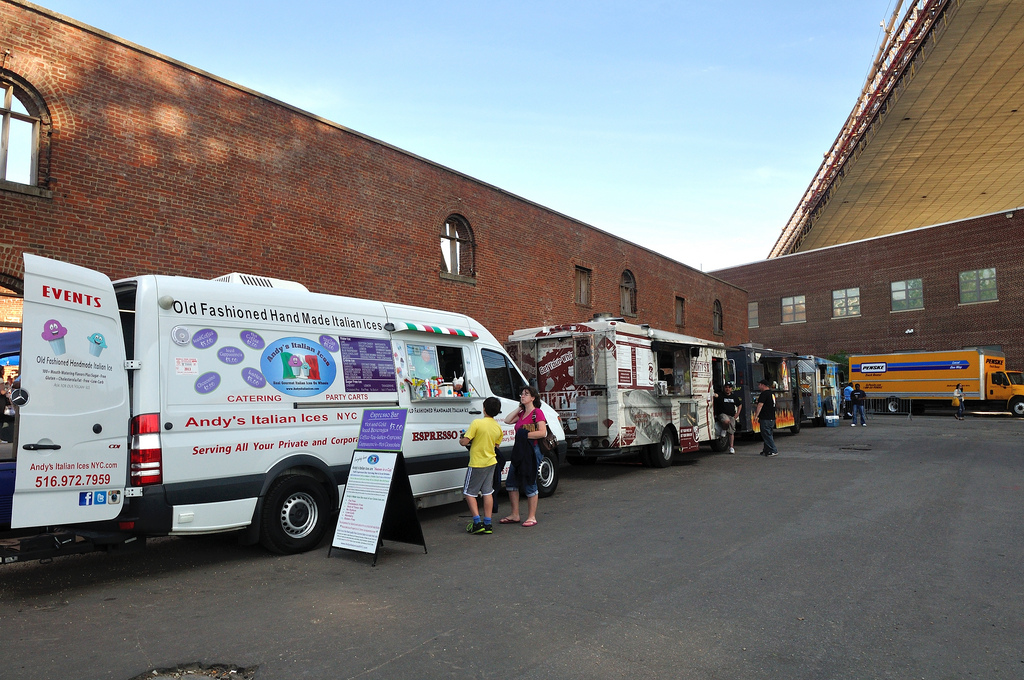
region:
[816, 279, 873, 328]
window on the building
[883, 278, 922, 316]
window on the building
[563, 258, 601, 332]
window on the building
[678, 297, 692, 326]
window on the building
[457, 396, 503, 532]
A brown haired boy in yellow shirt.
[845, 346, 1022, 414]
A long orange Penske truck.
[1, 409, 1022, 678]
A long dark grey paved drive way.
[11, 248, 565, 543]
A long white italian ice van.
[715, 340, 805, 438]
A black food truck with flames.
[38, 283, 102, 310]
Red word EVENTS on a white van.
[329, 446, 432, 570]
A black and white board outside a white van.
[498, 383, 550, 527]
A dark haired woman in pink.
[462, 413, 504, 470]
A yellow t-shirt.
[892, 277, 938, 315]
window on the building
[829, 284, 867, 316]
window on the building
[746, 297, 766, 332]
window on the building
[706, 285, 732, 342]
window on the building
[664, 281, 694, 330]
window on the building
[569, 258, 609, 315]
window on the building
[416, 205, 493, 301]
window on the building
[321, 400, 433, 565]
advertising board in front of food van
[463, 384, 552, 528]
two people standing in front of food van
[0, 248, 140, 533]
back door open on the food van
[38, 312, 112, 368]
faces on the italian ices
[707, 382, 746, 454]
person leaning against the food truck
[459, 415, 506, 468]
boy is wearing a yellow shirt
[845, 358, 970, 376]
blue stripe on the moving truck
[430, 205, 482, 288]
window is arched at the top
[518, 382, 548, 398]
the hair of a woman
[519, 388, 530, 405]
the face of a woman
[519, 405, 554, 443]
the arm of a woman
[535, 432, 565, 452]
the elbow of a woman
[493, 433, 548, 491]
the jacket of a woman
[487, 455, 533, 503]
the pants of a woman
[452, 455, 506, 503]
the shorts of a kid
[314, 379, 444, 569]
purple and white sign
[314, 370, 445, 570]
purple and white sign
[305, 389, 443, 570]
purple and white sign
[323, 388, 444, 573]
purple and white sign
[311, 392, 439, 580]
purple and white sign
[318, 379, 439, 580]
purple and white sign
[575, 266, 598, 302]
A window on a building.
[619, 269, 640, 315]
A window on a building.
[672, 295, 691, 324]
A window on a building.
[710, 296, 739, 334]
A window on a building.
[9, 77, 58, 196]
A window on a building.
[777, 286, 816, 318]
A window on a building.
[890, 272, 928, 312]
A window on a building.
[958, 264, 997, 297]
A window on a building.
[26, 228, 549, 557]
white van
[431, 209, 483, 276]
window in brick wall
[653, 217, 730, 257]
white clouds in blue sky